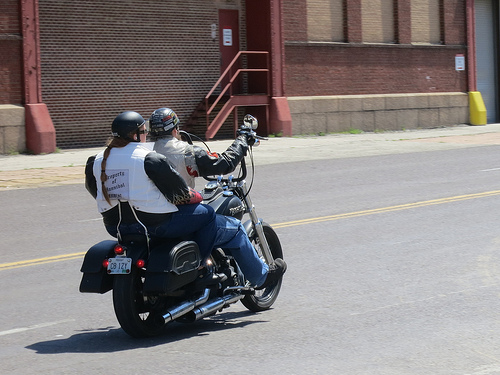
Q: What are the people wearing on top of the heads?
A: Helmets.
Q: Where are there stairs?
A: By building.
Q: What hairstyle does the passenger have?
A: Braid.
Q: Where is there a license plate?
A: Back of bike.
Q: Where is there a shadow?
A: On the ground.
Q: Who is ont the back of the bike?
A: A woman.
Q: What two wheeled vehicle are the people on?
A: Motorcycle.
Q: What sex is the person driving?
A: Male.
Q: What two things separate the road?
A: Lines.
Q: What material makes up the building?
A: Brick.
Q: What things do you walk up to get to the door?
A: Stairs.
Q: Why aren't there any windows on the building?
A: Bricked up.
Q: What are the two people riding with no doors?
A: Motorcycle.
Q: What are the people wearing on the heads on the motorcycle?
A: Helmets.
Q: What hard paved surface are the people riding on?
A: Concrete.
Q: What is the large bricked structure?
A: A building.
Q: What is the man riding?
A: Motorcycle.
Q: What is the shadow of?
A: Motorcycle.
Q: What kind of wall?
A: Brick.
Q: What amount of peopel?
A: Two.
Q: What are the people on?
A: Bike.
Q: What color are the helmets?
A: Black.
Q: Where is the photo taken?
A: Street.